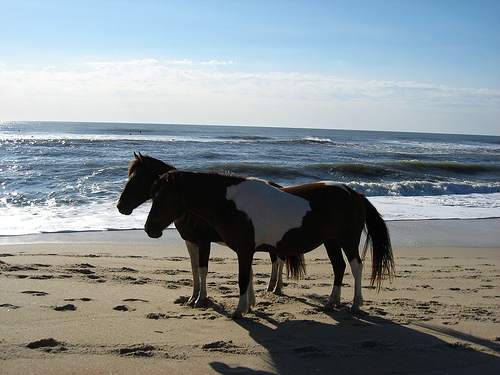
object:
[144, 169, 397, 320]
horse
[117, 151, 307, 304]
horse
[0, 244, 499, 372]
beach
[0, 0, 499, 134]
sky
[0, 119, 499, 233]
water